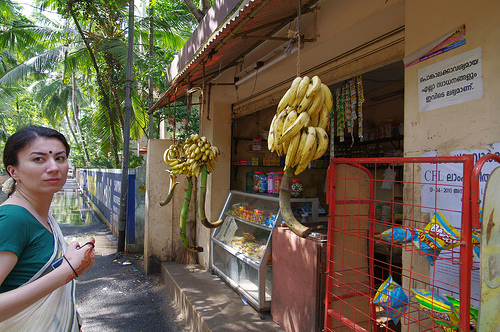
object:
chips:
[413, 210, 463, 266]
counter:
[209, 191, 319, 319]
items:
[247, 165, 318, 193]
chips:
[371, 277, 409, 325]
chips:
[409, 287, 458, 332]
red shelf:
[321, 151, 498, 329]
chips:
[375, 227, 417, 244]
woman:
[0, 124, 96, 332]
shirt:
[0, 204, 58, 299]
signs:
[417, 47, 482, 113]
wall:
[197, 85, 231, 267]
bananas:
[277, 110, 309, 145]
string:
[294, 34, 302, 76]